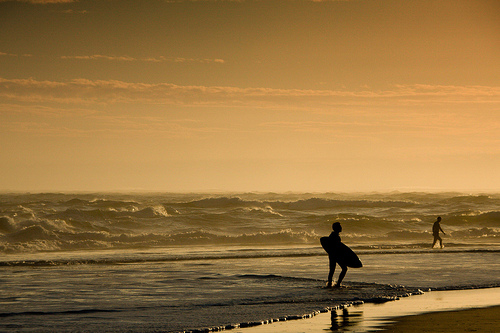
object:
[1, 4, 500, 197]
sky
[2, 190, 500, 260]
sea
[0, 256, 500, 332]
shore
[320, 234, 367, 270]
board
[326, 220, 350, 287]
man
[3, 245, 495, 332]
beach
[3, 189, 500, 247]
wave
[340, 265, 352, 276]
knee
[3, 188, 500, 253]
water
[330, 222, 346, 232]
head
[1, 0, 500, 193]
clouds